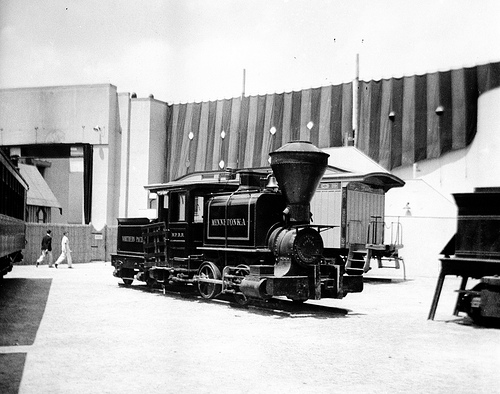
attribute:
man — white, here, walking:
[36, 226, 56, 265]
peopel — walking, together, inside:
[48, 229, 78, 265]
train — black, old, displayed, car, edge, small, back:
[127, 163, 325, 311]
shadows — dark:
[312, 302, 341, 317]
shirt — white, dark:
[62, 244, 65, 246]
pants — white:
[32, 255, 51, 257]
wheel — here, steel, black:
[186, 250, 226, 301]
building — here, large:
[69, 99, 145, 187]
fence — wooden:
[308, 97, 339, 109]